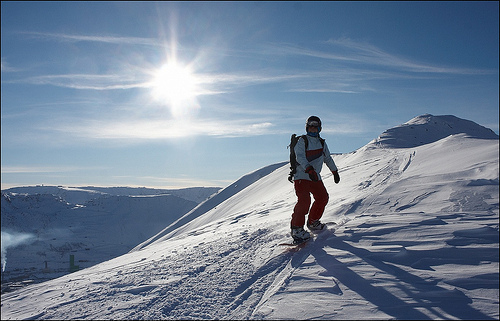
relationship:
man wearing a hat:
[290, 114, 340, 239] [301, 111, 323, 129]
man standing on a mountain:
[290, 114, 340, 239] [5, 162, 208, 292]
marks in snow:
[13, 213, 317, 319] [0, 114, 497, 320]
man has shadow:
[286, 113, 343, 242] [298, 228, 490, 318]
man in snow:
[286, 113, 343, 242] [0, 114, 497, 320]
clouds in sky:
[286, 39, 461, 101] [1, 0, 496, 177]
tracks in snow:
[2, 213, 320, 320] [0, 114, 497, 320]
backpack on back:
[284, 130, 326, 181] [290, 127, 297, 184]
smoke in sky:
[30, 26, 481, 136] [12, 18, 472, 153]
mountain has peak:
[0, 106, 498, 319] [357, 113, 494, 153]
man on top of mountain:
[290, 114, 340, 239] [0, 114, 498, 319]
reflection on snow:
[335, 224, 449, 319] [0, 114, 497, 320]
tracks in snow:
[360, 147, 406, 196] [0, 114, 497, 320]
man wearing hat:
[286, 113, 343, 242] [306, 115, 322, 125]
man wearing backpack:
[290, 114, 340, 239] [289, 130, 306, 181]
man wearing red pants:
[290, 114, 340, 239] [288, 167, 373, 253]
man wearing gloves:
[290, 114, 340, 239] [301, 169, 343, 187]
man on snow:
[290, 114, 340, 239] [0, 114, 497, 320]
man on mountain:
[290, 114, 340, 239] [28, 112, 499, 312]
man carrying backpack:
[290, 114, 340, 239] [264, 122, 308, 188]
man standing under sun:
[290, 114, 340, 239] [139, 56, 212, 124]